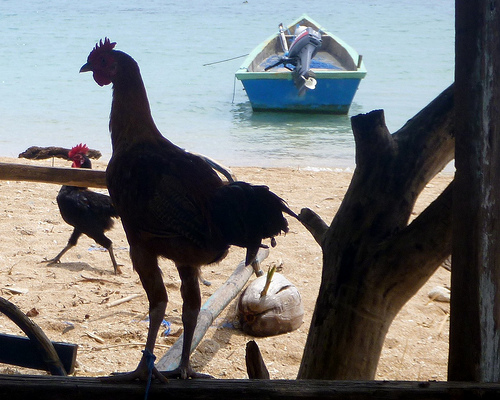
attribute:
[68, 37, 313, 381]
chicken — black, brown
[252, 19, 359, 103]
boat — bright blue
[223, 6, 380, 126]
boat — blue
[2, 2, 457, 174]
water — blue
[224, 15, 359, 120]
boat — small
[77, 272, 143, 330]
sticks — few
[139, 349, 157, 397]
string — blue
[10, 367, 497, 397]
wood — piece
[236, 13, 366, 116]
boat — black